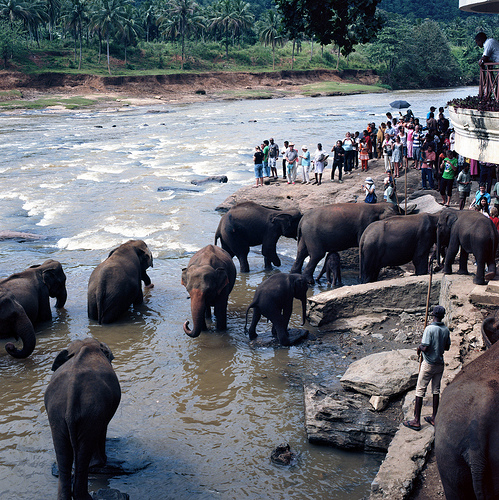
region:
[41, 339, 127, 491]
back of an elephant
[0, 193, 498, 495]
herd of elephants in the water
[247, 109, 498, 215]
crowd of people by the water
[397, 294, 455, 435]
man standing on a rock by the river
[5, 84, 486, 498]
river with medium flow rapids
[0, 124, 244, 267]
white river rapids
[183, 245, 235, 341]
elephant standint in the river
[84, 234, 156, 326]
elephant bathing in the river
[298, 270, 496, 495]
large boulders on the side of the river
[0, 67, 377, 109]
cliff on the side of the river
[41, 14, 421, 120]
This is a jungle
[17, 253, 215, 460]
These are elephants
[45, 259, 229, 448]
The elephants are bathing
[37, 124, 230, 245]
This is a river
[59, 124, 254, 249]
The river looks blue here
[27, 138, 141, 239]
There are rapids here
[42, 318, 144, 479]
the elephants are gray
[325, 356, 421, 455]
The ledge is made of rocks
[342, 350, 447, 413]
This is a flat rock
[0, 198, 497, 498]
A group of elephants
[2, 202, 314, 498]
Elephants are in the water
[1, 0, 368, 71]
Tall Trees in the background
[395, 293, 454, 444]
A man in the foreground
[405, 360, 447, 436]
Man is wearing shorts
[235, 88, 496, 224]
A group of people in the background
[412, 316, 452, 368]
Man is wearing a light blue shirt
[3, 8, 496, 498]
Photo was taken in the daytime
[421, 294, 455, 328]
Man has short hair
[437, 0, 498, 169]
Man is outside a white colored building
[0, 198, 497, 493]
elephants bathing in river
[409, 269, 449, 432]
man watching elephants bathing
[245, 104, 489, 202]
crowd of people watching elephants bathe in river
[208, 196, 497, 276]
elephants exiting river after bathing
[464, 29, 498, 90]
man watching elephants in river from balcony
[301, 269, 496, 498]
rock wall on river bank where elephants bathe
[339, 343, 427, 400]
large rock on river bank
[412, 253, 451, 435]
elephant tender in blue shirt and tan pants with pole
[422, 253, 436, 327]
thin wooden pole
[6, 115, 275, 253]
river rapids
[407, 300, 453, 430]
man standing by the river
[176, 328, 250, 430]
reflection of an elephant in the water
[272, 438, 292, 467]
small rock in the river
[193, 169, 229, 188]
rock in the river rapids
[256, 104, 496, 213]
crowd of peole looking at the elephants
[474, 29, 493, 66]
man on a balcony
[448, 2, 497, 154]
balcony next to a river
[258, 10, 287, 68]
palm tree in the distance next to the river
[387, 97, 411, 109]
large rock in the river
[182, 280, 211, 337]
trunk of an elephant